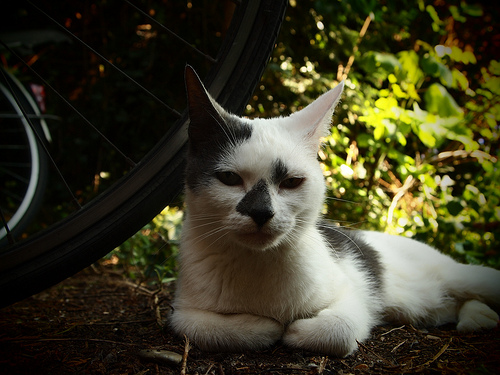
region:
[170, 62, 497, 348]
A gray and white cat.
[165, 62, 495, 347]
A cat laying down.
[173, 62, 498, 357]
A white and gray cat laying down.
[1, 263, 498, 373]
Brown dirty on the ground.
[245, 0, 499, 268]
Green bushes in the background.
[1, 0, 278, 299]
Bicycle wheel near cat.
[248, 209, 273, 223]
The cat has a gray nose.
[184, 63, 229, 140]
The cat has a gray ear.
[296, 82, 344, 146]
The cat has a white ear.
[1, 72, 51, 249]
A bicycle wheel further back.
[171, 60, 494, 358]
a cat lies next to a bicycle wheel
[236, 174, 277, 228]
the cat has a triangular gray patch above its nose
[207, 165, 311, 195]
the cat has gentle eyes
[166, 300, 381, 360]
the cat's front paws are tucked against its body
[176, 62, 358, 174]
the cat has one white ear and one gray ear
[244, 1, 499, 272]
there is green shrubbery behind the cat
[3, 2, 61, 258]
a second bicycle is parked next to the first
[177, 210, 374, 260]
the cat has white whiskers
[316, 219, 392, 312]
the cat has a gray patch on its side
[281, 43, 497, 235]
the background shrubbery is in the sun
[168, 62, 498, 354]
A black and white cat.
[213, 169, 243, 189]
Right eye of a cat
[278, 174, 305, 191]
A left eye of a cat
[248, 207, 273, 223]
Black nose of a cat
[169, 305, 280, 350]
Right front leg of a cat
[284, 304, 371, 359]
Left front leg of a cat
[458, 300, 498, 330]
a foot of a cat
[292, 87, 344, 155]
left ear of a cat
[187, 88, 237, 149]
right black ear of a cat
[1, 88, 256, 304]
a wheel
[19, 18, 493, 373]
a cat beside a bike tire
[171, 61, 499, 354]
a white and gray cat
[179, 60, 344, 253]
the head of a cat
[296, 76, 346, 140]
the ear of a cat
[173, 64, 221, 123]
the ear of a cat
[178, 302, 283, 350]
the leg of a cat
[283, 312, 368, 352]
the leg of a cat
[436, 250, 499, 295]
the tail of a cat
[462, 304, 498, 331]
the paw of a cat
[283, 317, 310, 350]
the paw of a cat